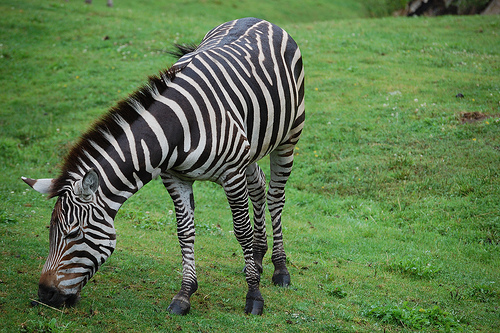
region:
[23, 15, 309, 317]
zebra standing on green grass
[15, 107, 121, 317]
zebra grazing on lightly sloped ground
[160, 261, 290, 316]
solid black hooves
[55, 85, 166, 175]
fuzzy and soft edge of mane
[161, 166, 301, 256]
horizontal stripes and curves across legs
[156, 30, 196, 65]
edge of tail hairs on far side of zebra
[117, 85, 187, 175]
thick black stripes on neck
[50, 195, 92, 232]
jumble of curved lines on forehead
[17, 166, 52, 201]
pointy gray ear with dark stripe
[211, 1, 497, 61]
lower ground behind zebra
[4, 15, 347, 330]
a zebra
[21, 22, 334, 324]
a black and white zebra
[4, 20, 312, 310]
a white and black zebra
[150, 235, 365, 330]
black hooves on a zebra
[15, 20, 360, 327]
a zebra eating grass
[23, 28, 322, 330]
a zebra eating green grass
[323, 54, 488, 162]
little flowers on a green grass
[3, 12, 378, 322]
a black and white striped zebra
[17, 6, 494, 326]
a zebra standing on grass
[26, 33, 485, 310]
a zebra standing on green grass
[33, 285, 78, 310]
the nose is back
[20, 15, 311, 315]
the zebra is striped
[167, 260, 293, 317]
the hooves are black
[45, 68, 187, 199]
the zebra has a mane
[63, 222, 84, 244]
the zebra has an eye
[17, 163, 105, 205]
the zebra has ears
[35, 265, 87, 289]
the zebra has brown above it's nose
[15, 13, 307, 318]
the zebra is black and white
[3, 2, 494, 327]
the grass is short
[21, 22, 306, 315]
black and white striped zebra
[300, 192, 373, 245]
short green and brown grass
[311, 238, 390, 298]
short green and brown grass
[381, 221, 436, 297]
short green and brown grass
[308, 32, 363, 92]
short green and brown grass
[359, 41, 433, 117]
short green and brown grass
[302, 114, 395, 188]
short green and brown grass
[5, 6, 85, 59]
short green and brown grass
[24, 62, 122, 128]
short green and brown grass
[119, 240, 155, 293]
short green and brown grass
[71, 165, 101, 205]
The right ear of a zebra.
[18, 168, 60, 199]
The left ear of a zebra.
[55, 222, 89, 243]
The left eye of a zebra.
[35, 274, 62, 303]
The nose of a zebra touching the ground.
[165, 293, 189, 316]
The right front hoof of a zebra.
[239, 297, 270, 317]
The left front foot of a zebra.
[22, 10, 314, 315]
A zebra eating in a field.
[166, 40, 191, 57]
The very tip of the zebra tail.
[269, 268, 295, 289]
The left rear hoof of a zebra.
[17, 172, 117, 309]
The head of a zebra.